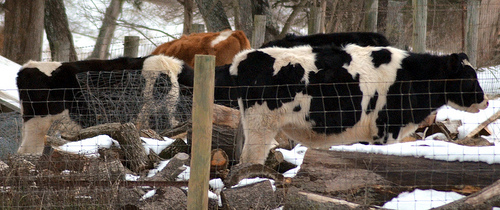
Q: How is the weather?
A: Cold.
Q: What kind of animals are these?
A: Cows.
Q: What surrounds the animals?
A: Fencing.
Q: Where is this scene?
A: Farm.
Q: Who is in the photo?
A: No one.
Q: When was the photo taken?
A: Evening.